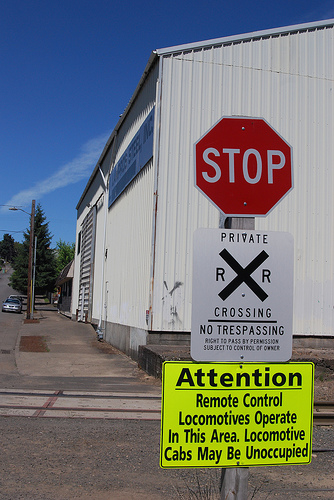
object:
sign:
[193, 114, 294, 219]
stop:
[202, 147, 285, 184]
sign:
[190, 228, 293, 362]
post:
[220, 216, 250, 500]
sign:
[159, 358, 315, 471]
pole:
[27, 199, 35, 321]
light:
[8, 208, 19, 211]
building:
[53, 18, 334, 364]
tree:
[9, 204, 59, 323]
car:
[2, 298, 22, 313]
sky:
[0, 0, 334, 252]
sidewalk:
[14, 312, 151, 374]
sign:
[108, 103, 154, 209]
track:
[0, 386, 334, 421]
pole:
[31, 236, 37, 318]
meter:
[96, 325, 106, 340]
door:
[78, 207, 96, 323]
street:
[0, 257, 26, 374]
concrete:
[138, 333, 334, 384]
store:
[53, 259, 73, 311]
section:
[19, 335, 50, 351]